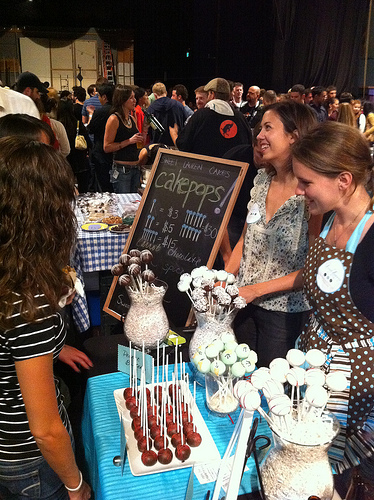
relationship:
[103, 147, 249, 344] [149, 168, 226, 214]
board advertising cakepops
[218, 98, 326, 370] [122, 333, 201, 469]
female selling cakepops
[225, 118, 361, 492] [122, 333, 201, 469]
female selling cakepops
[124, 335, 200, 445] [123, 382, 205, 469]
sticks in cakes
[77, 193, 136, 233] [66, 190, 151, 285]
food on table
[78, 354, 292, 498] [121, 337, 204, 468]
table with dessert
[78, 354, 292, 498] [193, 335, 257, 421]
table with dessert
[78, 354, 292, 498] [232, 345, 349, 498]
table with dessert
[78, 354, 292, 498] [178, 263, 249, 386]
table with dessert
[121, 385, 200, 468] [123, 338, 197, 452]
dessert balls on sticks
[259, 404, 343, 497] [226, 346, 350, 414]
vase with dessert balls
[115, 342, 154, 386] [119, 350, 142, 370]
card with name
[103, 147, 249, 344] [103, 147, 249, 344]
board with board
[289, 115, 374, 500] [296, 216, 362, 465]
female wearing apron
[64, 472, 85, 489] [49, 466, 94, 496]
bracelet on wrist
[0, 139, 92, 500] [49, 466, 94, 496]
lady has wrist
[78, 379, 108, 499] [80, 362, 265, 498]
table cloth on table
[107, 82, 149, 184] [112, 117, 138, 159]
woman wearing tanktop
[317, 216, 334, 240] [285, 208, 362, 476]
strap on apron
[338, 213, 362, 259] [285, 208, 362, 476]
strap on apron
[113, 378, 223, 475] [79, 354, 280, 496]
tray on tablecloth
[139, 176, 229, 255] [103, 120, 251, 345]
information on a board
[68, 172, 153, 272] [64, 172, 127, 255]
table with items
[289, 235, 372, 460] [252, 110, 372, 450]
apron on a woman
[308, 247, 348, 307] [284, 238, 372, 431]
button on apron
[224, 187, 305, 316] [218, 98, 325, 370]
blouse on female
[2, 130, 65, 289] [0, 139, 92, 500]
head of a lady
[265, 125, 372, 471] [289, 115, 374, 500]
head of a female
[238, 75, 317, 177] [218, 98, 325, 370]
head of a female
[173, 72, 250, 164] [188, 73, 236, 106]
head of a person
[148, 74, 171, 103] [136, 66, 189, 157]
head of a person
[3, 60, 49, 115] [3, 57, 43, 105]
head of a person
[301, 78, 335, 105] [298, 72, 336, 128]
head of a person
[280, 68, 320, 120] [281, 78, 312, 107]
head of a person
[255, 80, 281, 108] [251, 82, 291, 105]
head of a person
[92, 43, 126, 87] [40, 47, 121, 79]
ladder against wall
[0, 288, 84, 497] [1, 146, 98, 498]
lady wearing a shirt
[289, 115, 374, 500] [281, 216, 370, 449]
female wearing a apron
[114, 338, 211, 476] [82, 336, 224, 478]
cake pops on a plate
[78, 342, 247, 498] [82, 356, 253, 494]
table cloth on table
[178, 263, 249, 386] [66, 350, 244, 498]
dessert on table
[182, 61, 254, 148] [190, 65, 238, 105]
man wearing a hat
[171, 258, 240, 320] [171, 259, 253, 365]
cake pops in a vase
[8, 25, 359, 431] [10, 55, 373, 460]
crowd of people